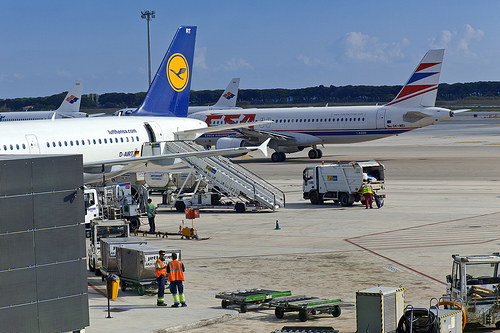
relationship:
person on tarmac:
[167, 252, 189, 306] [89, 115, 498, 332]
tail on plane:
[388, 48, 443, 141] [188, 46, 468, 166]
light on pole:
[138, 9, 157, 20] [146, 16, 153, 87]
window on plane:
[360, 118, 367, 122] [188, 46, 468, 166]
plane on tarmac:
[188, 46, 468, 166] [89, 115, 498, 332]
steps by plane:
[163, 138, 285, 211] [188, 46, 468, 166]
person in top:
[167, 252, 189, 306] [166, 260, 187, 282]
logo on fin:
[166, 50, 190, 93] [129, 24, 200, 119]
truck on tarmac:
[301, 161, 387, 207] [89, 115, 498, 332]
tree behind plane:
[316, 85, 329, 101] [188, 46, 468, 166]